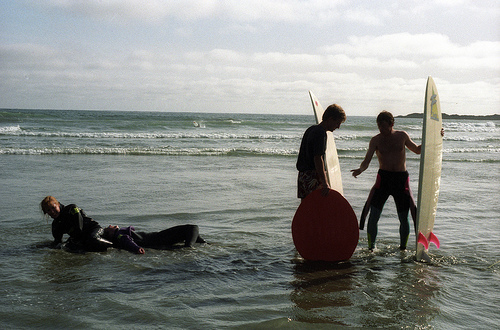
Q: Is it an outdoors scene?
A: Yes, it is outdoors.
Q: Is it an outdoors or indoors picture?
A: It is outdoors.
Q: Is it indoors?
A: No, it is outdoors.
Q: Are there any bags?
A: No, there are no bags.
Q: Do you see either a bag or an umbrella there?
A: No, there are no bags or umbrellas.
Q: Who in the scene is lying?
A: The people are lying.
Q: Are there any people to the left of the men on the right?
A: Yes, there are people to the left of the men.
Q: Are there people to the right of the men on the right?
A: No, the people are to the left of the men.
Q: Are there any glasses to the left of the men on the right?
A: No, there are people to the left of the men.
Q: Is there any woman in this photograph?
A: Yes, there is a woman.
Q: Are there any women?
A: Yes, there is a woman.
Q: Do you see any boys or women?
A: Yes, there is a woman.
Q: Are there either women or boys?
A: Yes, there is a woman.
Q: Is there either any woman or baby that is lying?
A: Yes, the woman is lying.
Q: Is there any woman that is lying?
A: Yes, there is a woman that is lying.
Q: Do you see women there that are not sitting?
A: Yes, there is a woman that is lying .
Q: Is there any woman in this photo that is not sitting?
A: Yes, there is a woman that is lying.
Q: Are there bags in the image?
A: No, there are no bags.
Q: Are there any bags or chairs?
A: No, there are no bags or chairs.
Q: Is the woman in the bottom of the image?
A: Yes, the woman is in the bottom of the image.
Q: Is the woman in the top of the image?
A: No, the woman is in the bottom of the image.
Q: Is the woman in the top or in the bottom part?
A: The woman is in the bottom of the image.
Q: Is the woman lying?
A: Yes, the woman is lying.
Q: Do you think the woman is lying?
A: Yes, the woman is lying.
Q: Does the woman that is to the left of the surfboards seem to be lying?
A: Yes, the woman is lying.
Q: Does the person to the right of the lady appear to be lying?
A: Yes, the woman is lying.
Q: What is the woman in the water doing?
A: The woman is lying.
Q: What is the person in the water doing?
A: The woman is lying.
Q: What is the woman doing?
A: The woman is lying.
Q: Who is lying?
A: The woman is lying.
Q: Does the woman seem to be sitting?
A: No, the woman is lying.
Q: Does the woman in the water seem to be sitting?
A: No, the woman is lying.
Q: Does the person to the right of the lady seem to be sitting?
A: No, the woman is lying.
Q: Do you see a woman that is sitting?
A: No, there is a woman but she is lying.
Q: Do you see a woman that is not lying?
A: No, there is a woman but she is lying.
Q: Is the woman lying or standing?
A: The woman is lying.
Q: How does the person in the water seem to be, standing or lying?
A: The woman is lying.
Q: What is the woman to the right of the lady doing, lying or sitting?
A: The woman is lying.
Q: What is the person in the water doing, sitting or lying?
A: The woman is lying.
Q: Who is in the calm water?
A: The woman is in the water.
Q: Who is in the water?
A: The woman is in the water.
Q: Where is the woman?
A: The woman is in the water.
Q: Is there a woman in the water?
A: Yes, there is a woman in the water.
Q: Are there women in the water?
A: Yes, there is a woman in the water.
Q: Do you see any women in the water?
A: Yes, there is a woman in the water.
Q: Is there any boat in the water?
A: No, there is a woman in the water.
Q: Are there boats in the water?
A: No, there is a woman in the water.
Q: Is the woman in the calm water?
A: Yes, the woman is in the water.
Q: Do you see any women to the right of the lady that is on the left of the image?
A: Yes, there is a woman to the right of the lady.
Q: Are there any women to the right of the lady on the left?
A: Yes, there is a woman to the right of the lady.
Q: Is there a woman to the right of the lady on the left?
A: Yes, there is a woman to the right of the lady.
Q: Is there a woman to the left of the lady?
A: No, the woman is to the right of the lady.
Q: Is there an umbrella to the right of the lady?
A: No, there is a woman to the right of the lady.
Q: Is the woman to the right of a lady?
A: Yes, the woman is to the right of a lady.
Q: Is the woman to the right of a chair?
A: No, the woman is to the right of a lady.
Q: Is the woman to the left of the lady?
A: No, the woman is to the right of the lady.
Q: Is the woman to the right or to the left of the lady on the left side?
A: The woman is to the right of the lady.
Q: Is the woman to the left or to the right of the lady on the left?
A: The woman is to the right of the lady.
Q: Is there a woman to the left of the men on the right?
A: Yes, there is a woman to the left of the men.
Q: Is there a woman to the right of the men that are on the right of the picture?
A: No, the woman is to the left of the men.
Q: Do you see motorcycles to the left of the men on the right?
A: No, there is a woman to the left of the men.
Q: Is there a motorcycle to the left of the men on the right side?
A: No, there is a woman to the left of the men.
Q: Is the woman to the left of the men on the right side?
A: Yes, the woman is to the left of the men.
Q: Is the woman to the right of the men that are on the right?
A: No, the woman is to the left of the men.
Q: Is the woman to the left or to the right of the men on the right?
A: The woman is to the left of the men.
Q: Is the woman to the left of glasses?
A: No, the woman is to the left of the surfboards.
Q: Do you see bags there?
A: No, there are no bags.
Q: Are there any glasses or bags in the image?
A: No, there are no bags or glasses.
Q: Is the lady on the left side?
A: Yes, the lady is on the left of the image.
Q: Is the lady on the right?
A: No, the lady is on the left of the image.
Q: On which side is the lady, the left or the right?
A: The lady is on the left of the image.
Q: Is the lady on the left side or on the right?
A: The lady is on the left of the image.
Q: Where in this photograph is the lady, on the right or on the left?
A: The lady is on the left of the image.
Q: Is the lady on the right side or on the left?
A: The lady is on the left of the image.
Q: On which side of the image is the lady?
A: The lady is on the left of the image.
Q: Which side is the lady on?
A: The lady is on the left of the image.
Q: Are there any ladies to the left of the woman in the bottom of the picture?
A: Yes, there is a lady to the left of the woman.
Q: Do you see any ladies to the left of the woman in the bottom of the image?
A: Yes, there is a lady to the left of the woman.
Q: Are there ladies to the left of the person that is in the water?
A: Yes, there is a lady to the left of the woman.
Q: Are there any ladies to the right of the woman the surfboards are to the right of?
A: No, the lady is to the left of the woman.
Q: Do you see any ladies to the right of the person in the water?
A: No, the lady is to the left of the woman.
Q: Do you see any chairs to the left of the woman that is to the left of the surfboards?
A: No, there is a lady to the left of the woman.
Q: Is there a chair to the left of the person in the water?
A: No, there is a lady to the left of the woman.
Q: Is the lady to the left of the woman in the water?
A: Yes, the lady is to the left of the woman.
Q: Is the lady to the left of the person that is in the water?
A: Yes, the lady is to the left of the woman.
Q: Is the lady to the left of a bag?
A: No, the lady is to the left of the woman.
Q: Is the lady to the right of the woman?
A: No, the lady is to the left of the woman.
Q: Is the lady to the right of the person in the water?
A: No, the lady is to the left of the woman.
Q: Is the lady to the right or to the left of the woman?
A: The lady is to the left of the woman.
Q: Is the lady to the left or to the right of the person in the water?
A: The lady is to the left of the woman.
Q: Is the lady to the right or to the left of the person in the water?
A: The lady is to the left of the woman.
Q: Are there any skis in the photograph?
A: No, there are no skis.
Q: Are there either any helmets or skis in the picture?
A: No, there are no skis or helmets.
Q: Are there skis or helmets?
A: No, there are no skis or helmets.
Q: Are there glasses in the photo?
A: No, there are no glasses.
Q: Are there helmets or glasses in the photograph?
A: No, there are no glasses or helmets.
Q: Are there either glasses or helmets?
A: No, there are no glasses or helmets.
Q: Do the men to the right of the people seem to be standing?
A: Yes, the men are standing.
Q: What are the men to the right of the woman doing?
A: The men are standing.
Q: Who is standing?
A: The men are standing.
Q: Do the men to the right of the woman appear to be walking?
A: No, the men are standing.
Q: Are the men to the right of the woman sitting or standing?
A: The men are standing.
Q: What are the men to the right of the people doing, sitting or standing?
A: The men are standing.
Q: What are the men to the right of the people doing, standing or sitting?
A: The men are standing.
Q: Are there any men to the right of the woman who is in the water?
A: Yes, there are men to the right of the woman.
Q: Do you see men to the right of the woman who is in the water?
A: Yes, there are men to the right of the woman.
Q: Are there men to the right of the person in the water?
A: Yes, there are men to the right of the woman.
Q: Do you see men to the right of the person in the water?
A: Yes, there are men to the right of the woman.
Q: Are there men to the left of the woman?
A: No, the men are to the right of the woman.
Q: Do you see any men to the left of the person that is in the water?
A: No, the men are to the right of the woman.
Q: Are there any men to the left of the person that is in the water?
A: No, the men are to the right of the woman.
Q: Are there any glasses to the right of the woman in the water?
A: No, there are men to the right of the woman.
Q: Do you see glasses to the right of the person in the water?
A: No, there are men to the right of the woman.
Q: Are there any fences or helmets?
A: No, there are no fences or helmets.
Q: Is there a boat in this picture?
A: No, there are no boats.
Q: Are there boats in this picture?
A: No, there are no boats.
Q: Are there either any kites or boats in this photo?
A: No, there are no boats or kites.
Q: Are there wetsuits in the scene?
A: Yes, there is a wetsuit.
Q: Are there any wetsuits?
A: Yes, there is a wetsuit.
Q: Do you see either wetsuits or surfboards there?
A: Yes, there is a wetsuit.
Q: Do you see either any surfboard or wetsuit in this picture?
A: Yes, there is a wetsuit.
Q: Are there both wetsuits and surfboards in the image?
A: Yes, there are both a wetsuit and a surfboard.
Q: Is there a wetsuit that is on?
A: Yes, there is a wetsuit that is on.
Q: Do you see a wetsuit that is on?
A: Yes, there is a wetsuit that is on.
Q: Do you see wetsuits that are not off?
A: Yes, there is a wetsuit that is on .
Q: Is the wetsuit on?
A: Yes, the wetsuit is on.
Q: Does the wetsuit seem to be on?
A: Yes, the wetsuit is on.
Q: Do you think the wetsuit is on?
A: Yes, the wetsuit is on.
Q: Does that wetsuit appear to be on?
A: Yes, the wetsuit is on.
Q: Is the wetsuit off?
A: No, the wetsuit is on.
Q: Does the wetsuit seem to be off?
A: No, the wetsuit is on.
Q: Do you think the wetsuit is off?
A: No, the wetsuit is on.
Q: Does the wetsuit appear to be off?
A: No, the wetsuit is on.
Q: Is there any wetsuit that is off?
A: No, there is a wetsuit but it is on.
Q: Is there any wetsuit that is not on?
A: No, there is a wetsuit but it is on.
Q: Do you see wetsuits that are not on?
A: No, there is a wetsuit but it is on.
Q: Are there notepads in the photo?
A: No, there are no notepads.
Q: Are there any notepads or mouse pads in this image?
A: No, there are no notepads or mouse pads.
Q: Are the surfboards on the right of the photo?
A: Yes, the surfboards are on the right of the image.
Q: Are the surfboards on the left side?
A: No, the surfboards are on the right of the image.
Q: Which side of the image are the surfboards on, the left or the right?
A: The surfboards are on the right of the image.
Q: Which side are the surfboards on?
A: The surfboards are on the right of the image.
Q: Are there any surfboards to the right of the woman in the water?
A: Yes, there are surfboards to the right of the woman.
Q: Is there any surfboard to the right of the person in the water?
A: Yes, there are surfboards to the right of the woman.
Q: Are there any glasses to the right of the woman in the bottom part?
A: No, there are surfboards to the right of the woman.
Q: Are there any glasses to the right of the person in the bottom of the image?
A: No, there are surfboards to the right of the woman.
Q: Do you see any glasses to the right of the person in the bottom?
A: No, there are surfboards to the right of the woman.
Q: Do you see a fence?
A: No, there are no fences.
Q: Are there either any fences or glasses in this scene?
A: No, there are no fences or glasses.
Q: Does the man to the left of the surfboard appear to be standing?
A: Yes, the man is standing.